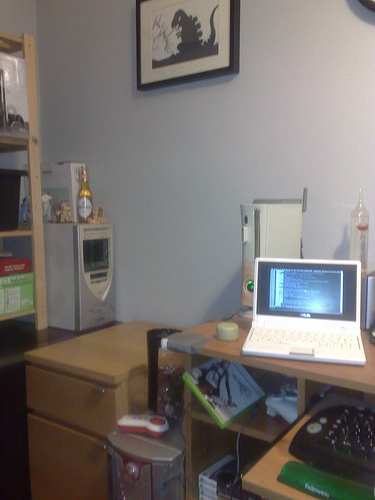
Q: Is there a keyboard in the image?
A: Yes, there is a keyboard.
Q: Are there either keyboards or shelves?
A: Yes, there is a keyboard.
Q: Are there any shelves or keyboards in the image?
A: Yes, there is a keyboard.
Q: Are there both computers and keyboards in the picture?
A: Yes, there are both a keyboard and a computer.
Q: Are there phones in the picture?
A: No, there are no phones.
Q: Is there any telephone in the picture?
A: No, there are no phones.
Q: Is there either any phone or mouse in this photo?
A: No, there are no phones or computer mice.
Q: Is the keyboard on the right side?
A: Yes, the keyboard is on the right of the image.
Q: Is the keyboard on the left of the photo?
A: No, the keyboard is on the right of the image.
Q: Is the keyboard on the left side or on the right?
A: The keyboard is on the right of the image.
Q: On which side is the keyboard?
A: The keyboard is on the right of the image.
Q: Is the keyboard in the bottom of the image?
A: Yes, the keyboard is in the bottom of the image.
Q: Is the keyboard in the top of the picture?
A: No, the keyboard is in the bottom of the image.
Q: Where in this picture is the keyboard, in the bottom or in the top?
A: The keyboard is in the bottom of the image.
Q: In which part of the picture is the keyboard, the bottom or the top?
A: The keyboard is in the bottom of the image.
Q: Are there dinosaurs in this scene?
A: Yes, there is a dinosaur.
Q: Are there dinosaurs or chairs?
A: Yes, there is a dinosaur.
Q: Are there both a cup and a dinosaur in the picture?
A: No, there is a dinosaur but no cups.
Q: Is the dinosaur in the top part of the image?
A: Yes, the dinosaur is in the top of the image.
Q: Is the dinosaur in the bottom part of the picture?
A: No, the dinosaur is in the top of the image.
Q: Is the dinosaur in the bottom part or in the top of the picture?
A: The dinosaur is in the top of the image.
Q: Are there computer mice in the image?
A: No, there are no computer mice.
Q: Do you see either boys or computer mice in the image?
A: No, there are no computer mice or boys.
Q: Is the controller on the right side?
A: Yes, the controller is on the right of the image.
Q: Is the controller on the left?
A: No, the controller is on the right of the image.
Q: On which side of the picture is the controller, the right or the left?
A: The controller is on the right of the image.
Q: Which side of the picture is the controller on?
A: The controller is on the right of the image.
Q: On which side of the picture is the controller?
A: The controller is on the right of the image.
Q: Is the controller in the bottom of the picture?
A: Yes, the controller is in the bottom of the image.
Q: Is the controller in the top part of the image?
A: No, the controller is in the bottom of the image.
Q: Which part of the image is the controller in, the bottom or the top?
A: The controller is in the bottom of the image.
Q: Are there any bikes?
A: No, there are no bikes.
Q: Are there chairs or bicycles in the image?
A: No, there are no bicycles or chairs.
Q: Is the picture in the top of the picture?
A: Yes, the picture is in the top of the image.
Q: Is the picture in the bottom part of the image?
A: No, the picture is in the top of the image.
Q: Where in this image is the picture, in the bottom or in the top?
A: The picture is in the top of the image.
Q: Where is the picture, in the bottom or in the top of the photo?
A: The picture is in the top of the image.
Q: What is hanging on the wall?
A: The picture is hanging on the wall.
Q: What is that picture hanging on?
A: The picture is hanging on the wall.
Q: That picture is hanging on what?
A: The picture is hanging on the wall.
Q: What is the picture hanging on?
A: The picture is hanging on the wall.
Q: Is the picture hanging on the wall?
A: Yes, the picture is hanging on the wall.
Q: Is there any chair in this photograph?
A: No, there are no chairs.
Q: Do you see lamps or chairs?
A: No, there are no chairs or lamps.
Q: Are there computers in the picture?
A: Yes, there is a computer.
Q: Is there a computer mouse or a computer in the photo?
A: Yes, there is a computer.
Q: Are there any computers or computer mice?
A: Yes, there is a computer.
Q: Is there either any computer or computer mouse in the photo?
A: Yes, there is a computer.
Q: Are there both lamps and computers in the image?
A: No, there is a computer but no lamps.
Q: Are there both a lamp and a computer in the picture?
A: No, there is a computer but no lamps.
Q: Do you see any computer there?
A: Yes, there is a computer.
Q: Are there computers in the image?
A: Yes, there is a computer.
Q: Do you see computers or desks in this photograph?
A: Yes, there is a computer.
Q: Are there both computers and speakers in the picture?
A: No, there is a computer but no speakers.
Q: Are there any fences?
A: No, there are no fences.